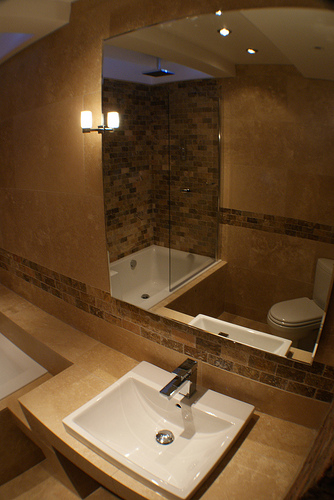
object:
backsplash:
[0, 248, 333, 404]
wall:
[0, 0, 333, 432]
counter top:
[0, 284, 320, 500]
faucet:
[159, 358, 198, 401]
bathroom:
[0, 0, 334, 500]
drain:
[155, 429, 174, 445]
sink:
[61, 359, 257, 500]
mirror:
[100, 7, 333, 366]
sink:
[187, 309, 326, 366]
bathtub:
[0, 330, 48, 400]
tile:
[83, 286, 105, 304]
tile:
[168, 134, 200, 181]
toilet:
[265, 296, 327, 338]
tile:
[77, 283, 138, 313]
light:
[80, 110, 92, 129]